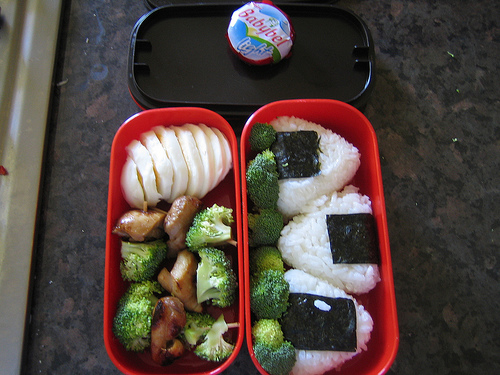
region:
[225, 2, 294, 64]
new baby bell light cheese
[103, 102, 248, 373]
red container with food inside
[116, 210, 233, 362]
broccoli and chicken within red container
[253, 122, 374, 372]
steamed rice and broccoli within container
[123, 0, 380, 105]
black lid to red container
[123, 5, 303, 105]
new babybel cheese sitting on black lid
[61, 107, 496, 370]
counter top that is holding up red container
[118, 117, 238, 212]
sliced hard boiled egg within red container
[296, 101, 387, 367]
steamed rice within red container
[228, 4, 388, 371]
new babybel cheese in front of red container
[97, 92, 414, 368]
Two red containers.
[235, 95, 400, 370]
Broccoli in a container.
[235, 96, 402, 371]
Rice in a container.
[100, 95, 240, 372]
Meat in a container.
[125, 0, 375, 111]
Black lid on a counter.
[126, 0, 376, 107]
Babybel cheese on a lid.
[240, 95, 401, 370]
Container with vegetables.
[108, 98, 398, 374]
Two containers of food.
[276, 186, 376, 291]
Seaweed on some rice.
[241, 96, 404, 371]
Container with some seaweed.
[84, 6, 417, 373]
a bento box meal with two sections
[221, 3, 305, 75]
a circle of Babybel cheese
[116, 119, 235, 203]
a sliced piece of white food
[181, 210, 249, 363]
three broccoli chunks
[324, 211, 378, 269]
a piece of seaweed on top of the rice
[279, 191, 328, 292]
white rice in the bento box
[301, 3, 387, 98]
a black cover to the bento box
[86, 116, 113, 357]
a red edge of the bento box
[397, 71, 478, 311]
the grey marble top of the table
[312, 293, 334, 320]
a grain of white rice on top of the seaweed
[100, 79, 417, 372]
There is food in the tray.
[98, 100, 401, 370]
The tray is red.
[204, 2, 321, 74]
The cheese is Babybel brand.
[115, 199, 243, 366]
There is broccoli in the tray.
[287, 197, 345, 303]
There is rice in the tray.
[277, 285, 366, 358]
There is seaweed in the tray.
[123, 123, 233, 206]
There is cheese in the tray.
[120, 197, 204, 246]
There is chicken in the tray.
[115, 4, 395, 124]
The lid is off the tray.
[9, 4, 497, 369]
The trays sit on a countertop.